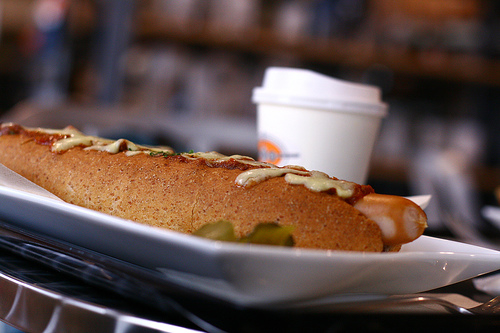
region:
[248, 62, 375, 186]
White, gray and orange cup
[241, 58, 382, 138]
White lid of cup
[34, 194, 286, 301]
White plate holding pizza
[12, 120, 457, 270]
Pizza with cheese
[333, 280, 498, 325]
Shiny silver spoon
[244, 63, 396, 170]
White paper cup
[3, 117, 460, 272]
Pizza with cheese and sauce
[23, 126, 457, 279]
Cheese pizza with sauce on plate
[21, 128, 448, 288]
Pizza with melted cheese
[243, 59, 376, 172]
coffee cup with white top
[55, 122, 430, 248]
hot dog on white plate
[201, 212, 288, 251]
green pickles on plate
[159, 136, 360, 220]
cheese on hot dog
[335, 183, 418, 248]
end of hot dog on plate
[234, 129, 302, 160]
orange logo on white cup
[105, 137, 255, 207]
large bread on hot dog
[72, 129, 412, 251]
hot dog smothered in various coverings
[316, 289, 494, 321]
fork utensil on side of plate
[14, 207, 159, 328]
countertop on side of bar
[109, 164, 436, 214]
this is a hot dog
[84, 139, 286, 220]
the hot dog is brown in color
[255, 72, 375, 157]
a white cup is beside the plate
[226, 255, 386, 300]
the hot dog is on a plate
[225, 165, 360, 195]
the hot dog is creamy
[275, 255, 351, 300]
the plate is white in color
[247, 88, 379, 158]
the cup is closed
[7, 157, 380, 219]
the hot dog is long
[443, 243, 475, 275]
the plate is shiny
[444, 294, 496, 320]
a plate is under the plate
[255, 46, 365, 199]
the cup is white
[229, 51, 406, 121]
the cover is white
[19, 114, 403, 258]
the bread is brown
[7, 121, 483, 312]
the plate is white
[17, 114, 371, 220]
there is salsa on top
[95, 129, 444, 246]
the hotdog is in the bread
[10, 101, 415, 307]
the hot dog is long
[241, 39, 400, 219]
there is only one cup on the table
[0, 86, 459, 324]
the plate is rectangle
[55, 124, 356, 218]
the mayo is beige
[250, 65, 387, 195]
white disposable cup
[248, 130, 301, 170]
orange logo on a disposable cup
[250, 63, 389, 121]
plastic lid on a paper cup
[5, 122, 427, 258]
really long hotdog in a bun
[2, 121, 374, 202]
two kinds on condiments on a hotdog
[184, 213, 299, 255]
slice of pickle next to the hot dog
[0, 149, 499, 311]
clean white ceramic plate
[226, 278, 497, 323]
shiny silverware next to the plate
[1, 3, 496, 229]
the blurry background of a restaurant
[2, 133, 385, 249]
the brown crust of a hot dog bun